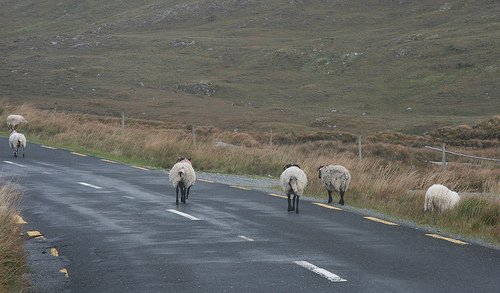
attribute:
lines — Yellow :
[306, 189, 498, 281]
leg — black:
[278, 196, 296, 212]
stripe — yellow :
[164, 200, 200, 225]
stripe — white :
[47, 239, 58, 256]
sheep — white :
[403, 163, 480, 235]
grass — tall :
[356, 150, 420, 210]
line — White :
[167, 201, 199, 227]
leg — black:
[172, 183, 182, 207]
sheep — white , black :
[273, 160, 308, 212]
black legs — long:
[283, 189, 305, 212]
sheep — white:
[161, 157, 193, 217]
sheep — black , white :
[316, 163, 350, 205]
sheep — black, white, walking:
[160, 148, 205, 205]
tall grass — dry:
[291, 144, 498, 239]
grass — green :
[240, 49, 432, 122]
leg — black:
[174, 185, 179, 205]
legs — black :
[261, 183, 321, 219]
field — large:
[34, 27, 452, 256]